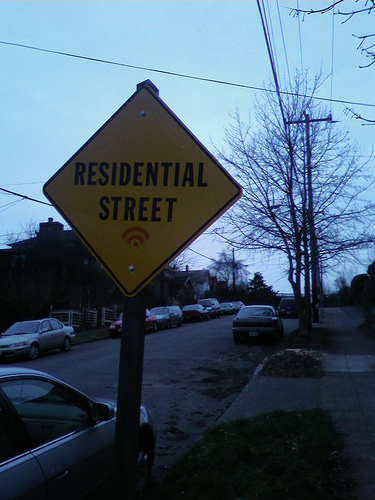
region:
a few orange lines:
[112, 224, 158, 250]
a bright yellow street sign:
[38, 80, 258, 310]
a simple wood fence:
[34, 283, 120, 343]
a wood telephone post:
[279, 77, 339, 315]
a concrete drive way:
[218, 368, 338, 439]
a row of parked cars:
[111, 293, 257, 339]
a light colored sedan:
[219, 298, 288, 352]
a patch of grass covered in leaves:
[253, 331, 331, 386]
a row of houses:
[23, 203, 256, 339]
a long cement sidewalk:
[299, 267, 369, 479]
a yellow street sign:
[41, 82, 248, 291]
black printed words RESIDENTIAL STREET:
[69, 157, 205, 219]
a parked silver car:
[0, 361, 155, 491]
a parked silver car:
[231, 303, 287, 346]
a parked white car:
[5, 319, 77, 359]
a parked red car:
[106, 306, 160, 334]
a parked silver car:
[149, 303, 182, 329]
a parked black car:
[183, 301, 210, 321]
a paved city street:
[0, 289, 281, 486]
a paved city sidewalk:
[316, 294, 373, 487]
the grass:
[214, 428, 286, 498]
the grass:
[237, 465, 263, 495]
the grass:
[231, 445, 258, 498]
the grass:
[247, 452, 267, 497]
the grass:
[238, 450, 281, 495]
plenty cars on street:
[153, 288, 235, 360]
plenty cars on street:
[162, 285, 227, 333]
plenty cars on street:
[138, 307, 221, 371]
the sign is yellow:
[113, 158, 177, 406]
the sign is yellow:
[95, 204, 173, 349]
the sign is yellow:
[78, 161, 202, 462]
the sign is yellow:
[150, 206, 214, 414]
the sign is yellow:
[136, 189, 208, 347]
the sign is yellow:
[117, 98, 226, 303]